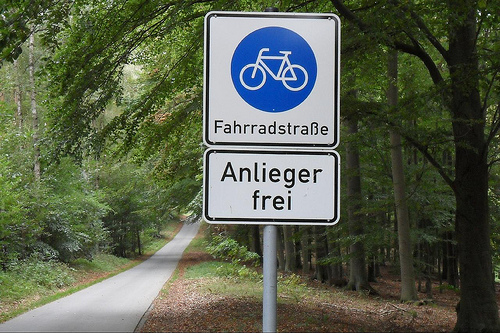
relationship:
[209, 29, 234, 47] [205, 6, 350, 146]
part of board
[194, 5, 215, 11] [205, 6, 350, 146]
edge of board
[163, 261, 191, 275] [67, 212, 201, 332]
edge of road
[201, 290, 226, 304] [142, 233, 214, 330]
leave by sidewal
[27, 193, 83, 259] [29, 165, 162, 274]
plane on hill